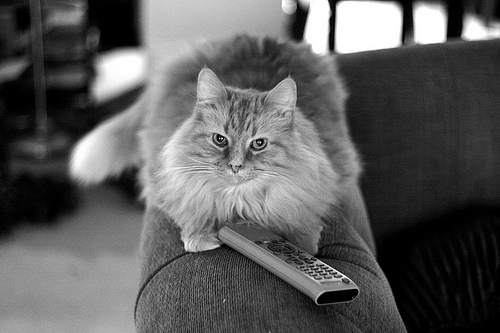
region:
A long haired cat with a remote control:
[132, 22, 374, 272]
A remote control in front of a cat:
[175, 99, 357, 316]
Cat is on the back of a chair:
[121, 12, 366, 261]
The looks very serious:
[165, 47, 332, 257]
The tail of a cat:
[70, 98, 153, 195]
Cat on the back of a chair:
[116, 27, 357, 273]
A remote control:
[220, 218, 365, 322]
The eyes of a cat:
[198, 117, 277, 168]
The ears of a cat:
[189, 66, 301, 124]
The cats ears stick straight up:
[182, 63, 314, 132]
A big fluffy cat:
[72, 30, 363, 252]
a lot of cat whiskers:
[163, 148, 220, 182]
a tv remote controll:
[213, 212, 358, 306]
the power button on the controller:
[341, 274, 351, 285]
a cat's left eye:
[248, 135, 267, 150]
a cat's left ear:
[264, 73, 298, 110]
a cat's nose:
[227, 155, 248, 174]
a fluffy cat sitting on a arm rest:
[66, 29, 414, 331]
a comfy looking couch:
[126, 36, 498, 331]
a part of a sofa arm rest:
[126, 198, 403, 325]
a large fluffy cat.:
[71, 5, 379, 314]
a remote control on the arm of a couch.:
[213, 174, 365, 322]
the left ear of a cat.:
[264, 57, 311, 117]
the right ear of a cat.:
[167, 62, 234, 117]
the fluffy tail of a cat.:
[63, 105, 160, 194]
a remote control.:
[200, 187, 375, 325]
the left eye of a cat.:
[241, 125, 281, 161]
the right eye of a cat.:
[209, 120, 232, 165]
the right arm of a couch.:
[120, 60, 415, 331]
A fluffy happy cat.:
[149, 49, 341, 216]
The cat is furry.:
[62, 25, 362, 267]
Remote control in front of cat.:
[64, 20, 358, 320]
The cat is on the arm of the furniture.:
[61, 20, 499, 330]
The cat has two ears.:
[59, 30, 359, 256]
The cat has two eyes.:
[64, 30, 364, 262]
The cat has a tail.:
[65, 30, 363, 265]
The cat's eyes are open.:
[63, 25, 370, 258]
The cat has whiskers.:
[143, 56, 322, 216]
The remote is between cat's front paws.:
[148, 64, 362, 314]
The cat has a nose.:
[148, 58, 343, 265]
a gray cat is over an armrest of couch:
[64, 27, 374, 259]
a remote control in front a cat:
[216, 208, 370, 314]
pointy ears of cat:
[192, 60, 300, 117]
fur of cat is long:
[68, 23, 373, 248]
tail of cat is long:
[63, 87, 145, 193]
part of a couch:
[139, 40, 499, 321]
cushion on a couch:
[384, 195, 498, 332]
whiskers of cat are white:
[159, 147, 299, 196]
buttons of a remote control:
[256, 228, 346, 283]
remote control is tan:
[218, 213, 363, 313]